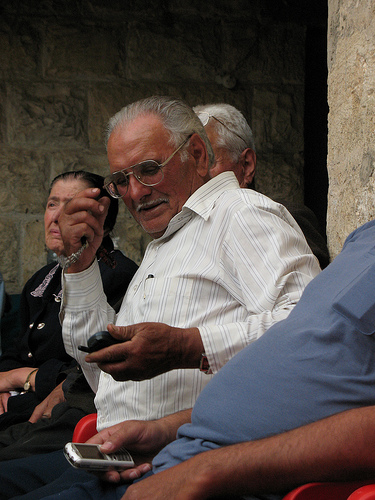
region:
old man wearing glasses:
[57, 102, 245, 241]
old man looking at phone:
[95, 113, 228, 288]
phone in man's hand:
[68, 310, 148, 374]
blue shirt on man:
[217, 226, 371, 439]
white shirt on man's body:
[126, 193, 282, 313]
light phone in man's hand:
[58, 429, 137, 478]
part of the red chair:
[64, 406, 105, 440]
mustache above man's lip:
[125, 190, 172, 220]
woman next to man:
[17, 158, 119, 289]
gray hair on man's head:
[220, 99, 252, 149]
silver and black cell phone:
[58, 439, 137, 475]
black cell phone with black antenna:
[71, 327, 119, 355]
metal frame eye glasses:
[98, 128, 205, 201]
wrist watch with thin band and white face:
[20, 365, 37, 392]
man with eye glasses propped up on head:
[192, 101, 257, 186]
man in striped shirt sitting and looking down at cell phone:
[4, 92, 320, 498]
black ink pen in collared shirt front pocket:
[137, 272, 193, 322]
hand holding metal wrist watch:
[51, 184, 112, 275]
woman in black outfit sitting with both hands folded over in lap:
[0, 166, 138, 449]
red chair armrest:
[70, 410, 95, 442]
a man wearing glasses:
[66, 91, 214, 210]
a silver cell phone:
[60, 428, 177, 498]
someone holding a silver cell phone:
[32, 374, 298, 496]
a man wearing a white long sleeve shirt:
[83, 105, 327, 380]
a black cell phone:
[61, 324, 181, 385]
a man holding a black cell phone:
[47, 106, 257, 365]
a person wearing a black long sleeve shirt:
[4, 163, 169, 358]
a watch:
[4, 350, 54, 409]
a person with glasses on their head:
[169, 87, 277, 208]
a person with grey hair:
[178, 99, 257, 189]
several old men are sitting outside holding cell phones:
[5, 90, 365, 486]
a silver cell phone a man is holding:
[64, 434, 139, 470]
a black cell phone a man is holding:
[68, 325, 121, 352]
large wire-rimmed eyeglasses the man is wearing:
[101, 159, 170, 191]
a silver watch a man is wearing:
[21, 368, 40, 393]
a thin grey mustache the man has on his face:
[131, 197, 168, 208]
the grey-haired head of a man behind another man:
[195, 101, 266, 184]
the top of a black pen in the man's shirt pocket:
[140, 272, 156, 281]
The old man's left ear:
[183, 134, 213, 180]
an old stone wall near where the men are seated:
[5, 82, 95, 162]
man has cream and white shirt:
[59, 115, 325, 499]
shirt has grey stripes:
[123, 216, 248, 327]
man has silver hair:
[59, 97, 294, 433]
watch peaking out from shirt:
[196, 334, 231, 373]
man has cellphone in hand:
[70, 405, 145, 492]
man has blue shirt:
[184, 314, 351, 430]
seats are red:
[69, 410, 144, 443]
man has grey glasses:
[85, 95, 223, 246]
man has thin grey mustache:
[128, 193, 190, 234]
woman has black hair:
[30, 150, 128, 387]